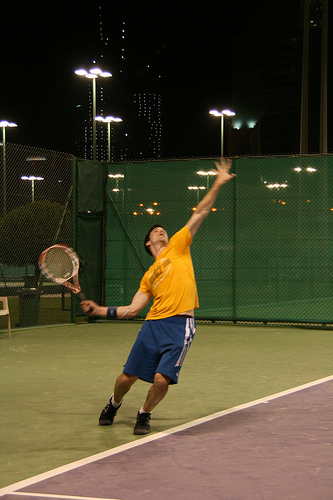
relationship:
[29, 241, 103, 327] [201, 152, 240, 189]
tennis racquet on hand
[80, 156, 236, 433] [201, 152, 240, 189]
man has hand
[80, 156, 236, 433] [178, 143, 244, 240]
man has arm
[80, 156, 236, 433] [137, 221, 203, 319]
man wearing shirt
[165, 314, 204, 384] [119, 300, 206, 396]
stripes are on shorts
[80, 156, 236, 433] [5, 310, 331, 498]
man on court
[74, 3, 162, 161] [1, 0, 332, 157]
skyscraper against sky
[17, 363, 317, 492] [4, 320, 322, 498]
white line on tennis court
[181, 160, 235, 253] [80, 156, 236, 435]
arm of man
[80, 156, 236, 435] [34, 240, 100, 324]
man holding racket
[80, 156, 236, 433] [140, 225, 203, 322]
man wearing shirt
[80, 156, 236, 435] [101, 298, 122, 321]
man wearing arnband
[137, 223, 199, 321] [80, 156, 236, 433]
yellow shirt on man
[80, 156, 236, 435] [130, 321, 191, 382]
man wearing blue shorts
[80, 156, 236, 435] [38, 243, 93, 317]
man holding racket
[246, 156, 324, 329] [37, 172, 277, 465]
fence behind man